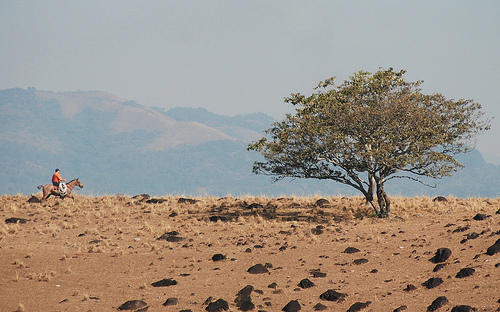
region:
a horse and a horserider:
[36, 167, 82, 202]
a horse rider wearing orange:
[52, 167, 63, 184]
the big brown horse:
[35, 178, 83, 202]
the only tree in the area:
[245, 67, 491, 210]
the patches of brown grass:
[80, 195, 141, 249]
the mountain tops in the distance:
[9, 82, 259, 169]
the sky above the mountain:
[17, 4, 344, 78]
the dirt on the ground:
[72, 258, 133, 288]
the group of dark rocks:
[141, 250, 472, 310]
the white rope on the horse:
[59, 181, 67, 191]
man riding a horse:
[35, 165, 86, 203]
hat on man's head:
[52, 167, 59, 174]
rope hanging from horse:
[58, 182, 67, 194]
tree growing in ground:
[242, 60, 493, 219]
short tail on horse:
[33, 182, 46, 190]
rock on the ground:
[112, 295, 161, 310]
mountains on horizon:
[4, 87, 499, 201]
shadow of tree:
[200, 194, 365, 221]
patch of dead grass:
[397, 197, 490, 212]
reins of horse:
[65, 181, 78, 188]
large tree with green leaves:
[239, 59, 488, 227]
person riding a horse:
[35, 164, 91, 207]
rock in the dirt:
[241, 261, 271, 278]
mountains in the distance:
[3, 80, 498, 215]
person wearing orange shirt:
[47, 166, 62, 193]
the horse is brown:
[29, 176, 85, 207]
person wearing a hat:
[47, 166, 66, 193]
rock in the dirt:
[115, 298, 150, 310]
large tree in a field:
[231, 66, 494, 224]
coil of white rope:
[57, 177, 69, 197]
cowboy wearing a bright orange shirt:
[50, 172, 62, 184]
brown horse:
[35, 176, 84, 203]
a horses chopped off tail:
[35, 182, 44, 191]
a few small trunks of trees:
[357, 184, 390, 219]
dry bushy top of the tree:
[244, 63, 496, 185]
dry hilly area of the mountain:
[28, 87, 259, 152]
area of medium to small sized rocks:
[115, 212, 499, 310]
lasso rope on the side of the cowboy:
[57, 180, 69, 197]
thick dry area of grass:
[390, 194, 499, 216]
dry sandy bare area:
[0, 253, 116, 310]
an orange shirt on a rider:
[52, 173, 60, 185]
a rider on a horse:
[37, 167, 93, 204]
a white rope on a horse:
[56, 181, 68, 197]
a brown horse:
[35, 174, 84, 204]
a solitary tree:
[254, 60, 487, 235]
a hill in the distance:
[6, 86, 498, 200]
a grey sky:
[2, 2, 498, 155]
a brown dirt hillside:
[1, 196, 496, 309]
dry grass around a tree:
[265, 196, 491, 227]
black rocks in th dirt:
[423, 238, 471, 291]